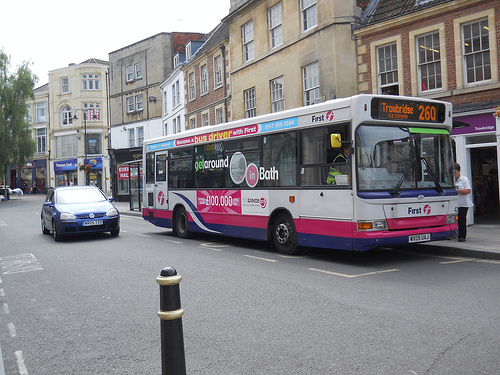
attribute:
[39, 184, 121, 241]
car — blue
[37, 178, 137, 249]
car — blue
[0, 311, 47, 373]
lines — broken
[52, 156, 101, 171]
sign — blue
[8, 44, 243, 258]
building — brick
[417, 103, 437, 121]
number — orange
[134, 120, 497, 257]
bus — red, white and blue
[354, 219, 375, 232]
light — orange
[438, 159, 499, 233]
person —  standing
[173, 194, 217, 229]
stripe — pink and blue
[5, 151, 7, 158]
leaf — green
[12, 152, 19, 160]
leaf — green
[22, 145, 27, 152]
leaf — green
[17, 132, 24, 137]
leaf — green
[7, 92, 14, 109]
leaf — green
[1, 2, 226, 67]
sky — daytime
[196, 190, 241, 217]
sign — pink and white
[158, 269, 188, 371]
pole — black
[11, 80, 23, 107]
leaves — green